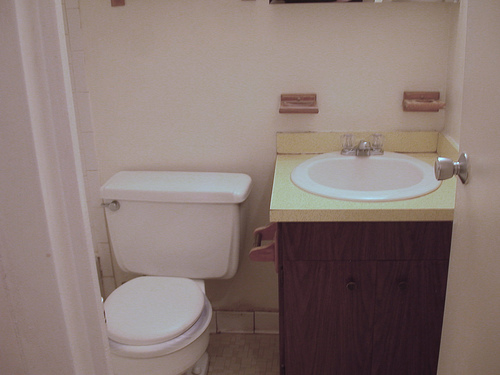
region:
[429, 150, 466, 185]
The door knob is silver.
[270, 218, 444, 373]
The cabinet is brown.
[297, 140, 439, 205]
The sink is white.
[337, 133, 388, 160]
The faucet is silver.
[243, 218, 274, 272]
The toilet paper holder is on the cabinet.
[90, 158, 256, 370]
The toilet is white.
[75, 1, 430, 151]
The wall is white.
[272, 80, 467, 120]
The soap holders are brown.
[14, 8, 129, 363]
The door is white.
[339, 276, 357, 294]
The knob is brown.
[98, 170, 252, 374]
a toilet set in the bathroom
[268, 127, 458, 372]
a sink fixture in the bathroom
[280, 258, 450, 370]
two doors to the bathroom's sink fixture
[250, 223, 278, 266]
toilet roll attached to the side of the sink fixture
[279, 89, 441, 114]
two soap dishes affixed to the bathroom's wall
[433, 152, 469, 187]
the turning knob on the bathroom's door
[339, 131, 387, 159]
the faucets to the sink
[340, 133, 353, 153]
the hot water knob to the faucet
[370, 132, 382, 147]
the cold water knob on the faucet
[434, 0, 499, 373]
an open door to the bathroom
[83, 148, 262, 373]
toilet of a bathroom is clean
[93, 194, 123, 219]
handle of bathroom is color silver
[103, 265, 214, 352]
lid of the bathroom is close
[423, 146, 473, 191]
knob of a bathroom door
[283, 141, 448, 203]
sink of bathroom is circle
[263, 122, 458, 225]
small counter of a bathroom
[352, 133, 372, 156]
faucet of a sink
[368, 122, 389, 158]
right handle of faucet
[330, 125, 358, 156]
left handle of faucet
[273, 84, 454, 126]
two soap dishes on top of sink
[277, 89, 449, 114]
two soap holders on wall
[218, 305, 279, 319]
mold along edge of tile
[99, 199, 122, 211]
chrome toilet handle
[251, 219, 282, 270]
pink and brown toilet paper holder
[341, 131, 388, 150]
clear handles on sink faucet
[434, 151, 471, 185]
chrome door knob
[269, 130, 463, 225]
yellow sink counter top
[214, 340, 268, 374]
patterned tile on floor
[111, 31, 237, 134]
white wall in background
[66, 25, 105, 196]
white subway tile in shower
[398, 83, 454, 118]
Cup and toothbrush holder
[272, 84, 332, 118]
Wooden soap tray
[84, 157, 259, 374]
White ceramic toilet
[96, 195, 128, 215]
Silver toilet flush handle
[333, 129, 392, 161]
Chrome faucet fixture with plastic handles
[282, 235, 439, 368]
Wooden base cabinet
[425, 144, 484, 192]
Brushed steel door knob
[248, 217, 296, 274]
Wooden toilet paper dispenser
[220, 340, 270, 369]
Tile work of white and beige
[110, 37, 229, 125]
A white painted wall